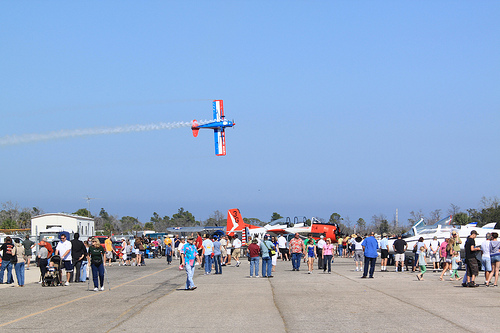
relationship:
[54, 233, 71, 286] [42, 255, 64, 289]
man pushing stroller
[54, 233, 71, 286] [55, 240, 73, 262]
man wearing shirt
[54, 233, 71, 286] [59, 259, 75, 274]
man wearing shorts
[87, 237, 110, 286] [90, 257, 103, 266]
woman wearing fanny pack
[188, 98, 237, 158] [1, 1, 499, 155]
plane in sky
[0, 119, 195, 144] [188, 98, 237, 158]
smoke behind plane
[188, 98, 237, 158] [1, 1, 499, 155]
plane flying in sky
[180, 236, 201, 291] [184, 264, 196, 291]
man wearing jeans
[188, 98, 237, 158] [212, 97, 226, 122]
plane has wing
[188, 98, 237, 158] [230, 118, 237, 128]
plane has propeller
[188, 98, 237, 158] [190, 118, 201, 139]
plane has tail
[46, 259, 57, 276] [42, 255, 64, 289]
child inside stroller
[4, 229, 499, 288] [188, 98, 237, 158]
people watching plane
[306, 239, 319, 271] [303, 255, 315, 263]
woman wearing shorts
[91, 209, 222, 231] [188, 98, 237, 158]
trees behind plane